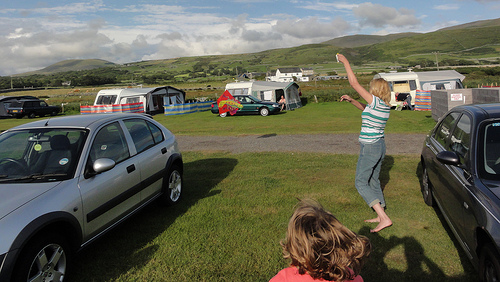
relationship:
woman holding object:
[335, 51, 394, 233] [334, 50, 341, 64]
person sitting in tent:
[276, 93, 286, 111] [225, 80, 305, 111]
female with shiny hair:
[263, 195, 367, 281] [282, 196, 373, 278]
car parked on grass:
[0, 115, 183, 281] [0, 147, 481, 281]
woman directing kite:
[335, 51, 394, 233] [217, 91, 243, 116]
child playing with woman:
[263, 195, 367, 281] [335, 51, 394, 233]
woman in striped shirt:
[335, 51, 394, 233] [358, 96, 390, 144]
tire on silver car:
[163, 165, 183, 205] [0, 115, 183, 281]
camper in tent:
[276, 93, 286, 111] [225, 80, 305, 111]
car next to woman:
[419, 104, 499, 282] [335, 51, 394, 233]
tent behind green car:
[225, 80, 305, 111] [211, 94, 280, 117]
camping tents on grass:
[225, 80, 305, 111] [0, 100, 440, 134]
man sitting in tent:
[276, 93, 286, 111] [225, 80, 305, 111]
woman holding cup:
[335, 51, 394, 233] [334, 50, 341, 64]